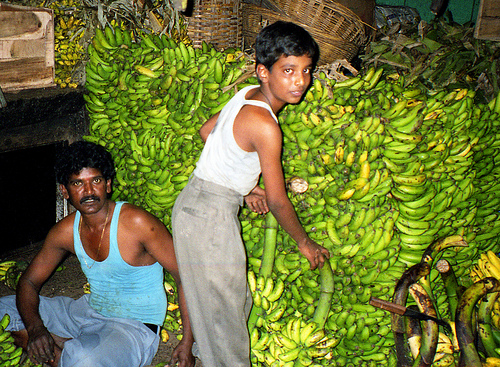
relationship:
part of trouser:
[199, 293, 238, 321] [163, 171, 263, 360]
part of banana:
[327, 302, 348, 322] [332, 307, 356, 328]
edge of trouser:
[243, 283, 260, 328] [163, 171, 263, 360]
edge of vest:
[114, 254, 137, 274] [57, 194, 185, 334]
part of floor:
[155, 322, 174, 345] [140, 330, 200, 365]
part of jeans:
[100, 332, 121, 350] [1, 290, 164, 364]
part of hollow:
[21, 163, 41, 197] [7, 153, 68, 256]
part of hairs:
[71, 145, 96, 155] [53, 140, 122, 185]